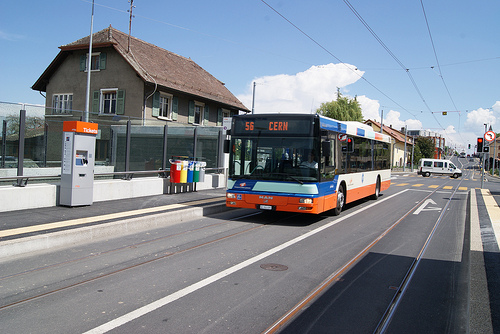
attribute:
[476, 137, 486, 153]
light — red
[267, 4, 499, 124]
cables — power lines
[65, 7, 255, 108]
roof — brown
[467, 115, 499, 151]
traffic sign — red, white, black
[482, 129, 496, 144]
traffic sign — no left turn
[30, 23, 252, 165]
building — brown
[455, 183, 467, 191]
stripe — yellow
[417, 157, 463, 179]
van — white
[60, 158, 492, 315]
road — asphalt, markings painted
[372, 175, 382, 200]
wheel — back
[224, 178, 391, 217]
stripe — orange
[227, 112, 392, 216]
bus — public